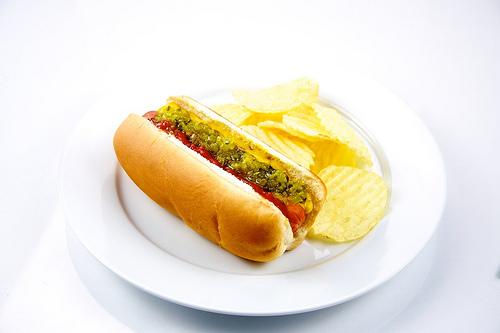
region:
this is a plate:
[69, 19, 451, 313]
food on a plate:
[80, 17, 441, 317]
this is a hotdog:
[118, 50, 351, 278]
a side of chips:
[199, 63, 384, 254]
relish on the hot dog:
[152, 105, 316, 217]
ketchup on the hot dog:
[143, 120, 295, 219]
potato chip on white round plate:
[214, 102, 249, 123]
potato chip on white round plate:
[234, 74, 320, 111]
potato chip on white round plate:
[284, 101, 340, 137]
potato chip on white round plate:
[311, 97, 377, 165]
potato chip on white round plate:
[302, 164, 387, 241]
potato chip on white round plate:
[254, 119, 320, 142]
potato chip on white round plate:
[242, 125, 314, 168]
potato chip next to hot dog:
[212, 98, 251, 127]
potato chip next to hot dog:
[243, 125, 314, 170]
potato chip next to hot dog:
[307, 166, 383, 241]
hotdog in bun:
[116, 92, 323, 252]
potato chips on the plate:
[215, 78, 378, 245]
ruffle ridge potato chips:
[220, 77, 377, 244]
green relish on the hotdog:
[165, 104, 312, 211]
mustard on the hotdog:
[167, 104, 312, 209]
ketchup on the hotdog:
[158, 114, 288, 214]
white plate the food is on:
[73, 49, 445, 319]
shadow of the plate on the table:
[68, 241, 442, 332]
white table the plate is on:
[8, 2, 499, 327]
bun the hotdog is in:
[115, 97, 323, 259]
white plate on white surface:
[7, 12, 492, 323]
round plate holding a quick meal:
[63, 50, 448, 315]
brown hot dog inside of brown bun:
[115, 90, 327, 265]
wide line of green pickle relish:
[155, 91, 310, 216]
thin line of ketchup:
[150, 105, 280, 215]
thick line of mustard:
[158, 96, 313, 216]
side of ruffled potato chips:
[215, 77, 389, 253]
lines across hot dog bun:
[205, 197, 280, 264]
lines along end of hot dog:
[284, 205, 306, 237]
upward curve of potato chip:
[232, 72, 316, 116]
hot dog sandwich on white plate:
[111, 91, 332, 264]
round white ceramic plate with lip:
[65, 63, 460, 319]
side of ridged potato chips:
[230, 68, 392, 254]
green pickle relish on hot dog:
[156, 115, 306, 212]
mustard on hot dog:
[156, 97, 315, 193]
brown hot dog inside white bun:
[138, 108, 308, 232]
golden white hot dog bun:
[103, 91, 329, 263]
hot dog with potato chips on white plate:
[74, 58, 455, 315]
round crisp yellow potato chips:
[219, 64, 392, 258]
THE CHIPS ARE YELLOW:
[220, 81, 386, 242]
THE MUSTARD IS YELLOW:
[174, 103, 314, 209]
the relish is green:
[165, 106, 304, 202]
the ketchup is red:
[155, 113, 276, 215]